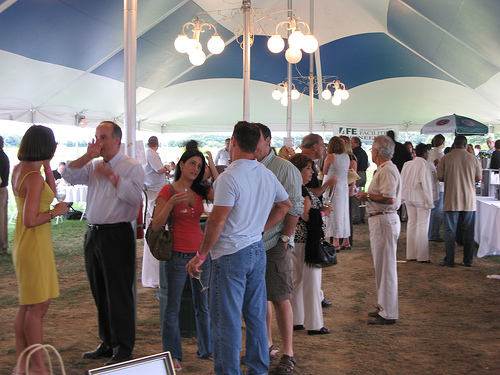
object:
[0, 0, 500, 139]
tent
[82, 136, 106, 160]
hands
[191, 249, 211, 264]
bracelet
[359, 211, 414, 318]
khaki pants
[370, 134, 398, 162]
hair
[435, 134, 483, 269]
man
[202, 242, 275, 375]
blue jeans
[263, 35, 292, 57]
light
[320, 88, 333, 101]
light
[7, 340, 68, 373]
handles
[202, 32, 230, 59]
lights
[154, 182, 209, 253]
shirt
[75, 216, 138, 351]
black pants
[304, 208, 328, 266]
scarf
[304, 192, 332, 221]
arm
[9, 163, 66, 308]
dress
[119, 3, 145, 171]
pole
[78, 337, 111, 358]
shoes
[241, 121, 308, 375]
man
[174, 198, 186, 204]
finger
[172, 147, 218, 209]
hair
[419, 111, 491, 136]
umbrella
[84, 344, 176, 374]
frame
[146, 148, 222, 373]
woman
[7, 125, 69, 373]
woman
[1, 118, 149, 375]
couple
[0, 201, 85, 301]
grass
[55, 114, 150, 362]
man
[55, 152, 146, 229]
shirt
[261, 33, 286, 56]
chandelier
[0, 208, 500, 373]
dirt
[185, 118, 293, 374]
man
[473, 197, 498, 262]
cloth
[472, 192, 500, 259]
table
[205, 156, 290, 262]
shirt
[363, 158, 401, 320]
formal wear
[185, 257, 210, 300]
glass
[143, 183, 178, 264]
purse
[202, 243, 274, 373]
jeans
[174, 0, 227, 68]
fixtures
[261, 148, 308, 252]
shirt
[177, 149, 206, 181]
head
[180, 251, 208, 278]
hand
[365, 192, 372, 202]
watch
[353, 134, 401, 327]
people